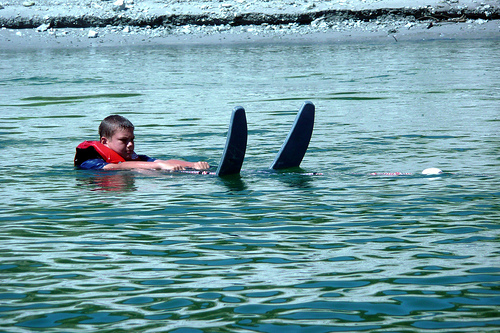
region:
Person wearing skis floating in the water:
[62, 97, 327, 216]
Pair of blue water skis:
[216, 80, 325, 182]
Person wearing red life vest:
[54, 105, 151, 173]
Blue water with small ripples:
[190, 200, 470, 310]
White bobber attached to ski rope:
[414, 157, 454, 189]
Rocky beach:
[62, 7, 329, 49]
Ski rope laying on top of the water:
[316, 159, 403, 188]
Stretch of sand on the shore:
[13, 40, 195, 53]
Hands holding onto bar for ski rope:
[158, 149, 216, 183]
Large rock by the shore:
[85, 25, 100, 42]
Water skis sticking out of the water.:
[203, 108, 333, 183]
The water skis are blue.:
[216, 102, 328, 162]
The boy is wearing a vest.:
[80, 135, 117, 170]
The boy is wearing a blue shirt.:
[76, 157, 114, 189]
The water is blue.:
[156, 252, 268, 299]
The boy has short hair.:
[87, 115, 137, 135]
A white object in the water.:
[411, 155, 454, 190]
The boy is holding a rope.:
[171, 150, 223, 177]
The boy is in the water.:
[42, 83, 436, 258]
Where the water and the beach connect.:
[0, 2, 497, 45]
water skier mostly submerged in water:
[55, 86, 346, 221]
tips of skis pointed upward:
[215, 90, 325, 192]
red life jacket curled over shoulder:
[60, 86, 145, 191]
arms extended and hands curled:
[96, 141, 206, 181]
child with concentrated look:
[95, 110, 140, 160]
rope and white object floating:
[181, 157, 446, 182]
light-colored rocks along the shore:
[20, 11, 457, 51]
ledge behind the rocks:
[15, 1, 492, 31]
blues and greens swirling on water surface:
[95, 230, 420, 292]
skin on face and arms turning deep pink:
[96, 105, 207, 190]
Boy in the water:
[66, 104, 217, 190]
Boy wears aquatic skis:
[61, 90, 326, 201]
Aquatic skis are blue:
[208, 90, 323, 195]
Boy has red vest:
[67, 102, 214, 192]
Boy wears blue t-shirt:
[65, 105, 215, 195]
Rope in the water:
[195, 160, 461, 187]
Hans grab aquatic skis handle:
[150, 148, 211, 178]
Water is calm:
[5, 38, 495, 329]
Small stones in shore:
[3, 0, 494, 40]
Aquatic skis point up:
[211, 81, 324, 188]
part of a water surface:
[363, 267, 448, 317]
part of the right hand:
[154, 163, 181, 172]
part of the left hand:
[194, 160, 212, 174]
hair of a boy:
[107, 112, 129, 126]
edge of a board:
[218, 120, 262, 172]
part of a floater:
[99, 146, 114, 161]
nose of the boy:
[126, 137, 138, 154]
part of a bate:
[407, 151, 454, 179]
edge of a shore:
[245, 12, 291, 42]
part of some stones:
[78, 27, 148, 56]